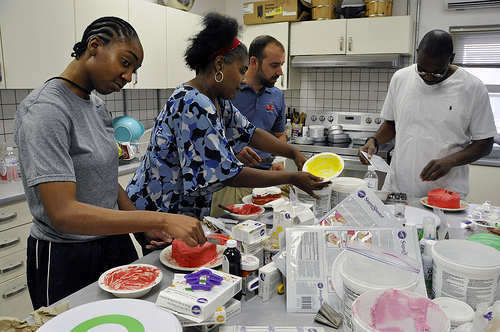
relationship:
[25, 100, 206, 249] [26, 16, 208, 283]
arm of lady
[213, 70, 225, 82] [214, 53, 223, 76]
earring on ear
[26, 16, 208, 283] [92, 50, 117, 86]
lady has a cheek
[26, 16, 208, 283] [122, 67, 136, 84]
lady has a nose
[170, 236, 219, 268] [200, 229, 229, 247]
cake being iced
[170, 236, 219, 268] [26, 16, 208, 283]
cake iced by lady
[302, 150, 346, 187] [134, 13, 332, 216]
dish held by woman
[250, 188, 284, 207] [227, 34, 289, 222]
cake iced by man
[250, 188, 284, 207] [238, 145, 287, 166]
cake being iced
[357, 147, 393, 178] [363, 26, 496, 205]
paper held by man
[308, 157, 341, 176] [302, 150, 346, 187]
icing in bowl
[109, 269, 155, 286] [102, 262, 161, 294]
icing in container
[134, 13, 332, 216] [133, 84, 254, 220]
woman wearing top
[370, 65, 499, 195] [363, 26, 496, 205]
t-shirt on man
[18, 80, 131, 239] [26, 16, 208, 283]
t-shirt on lady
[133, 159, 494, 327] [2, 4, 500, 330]
cooking in kitchen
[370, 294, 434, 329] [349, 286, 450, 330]
pink icing in bucket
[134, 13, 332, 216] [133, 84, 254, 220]
woman wearing blouse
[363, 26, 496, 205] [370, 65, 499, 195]
man wearing t-shirt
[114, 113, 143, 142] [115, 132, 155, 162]
bowl in dish drain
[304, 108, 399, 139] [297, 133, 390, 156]
back of stove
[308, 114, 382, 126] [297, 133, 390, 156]
control knobs on stove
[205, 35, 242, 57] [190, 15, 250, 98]
hair band on woman's head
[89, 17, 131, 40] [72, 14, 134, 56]
corn rows in hair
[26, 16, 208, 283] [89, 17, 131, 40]
lady with corn rows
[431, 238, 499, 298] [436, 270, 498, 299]
plastic bowl has writing on it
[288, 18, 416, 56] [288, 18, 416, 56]
cabinet has cabinet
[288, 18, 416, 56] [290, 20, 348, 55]
cabinet has door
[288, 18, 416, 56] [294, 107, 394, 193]
cabinet over oven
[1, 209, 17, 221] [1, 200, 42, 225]
silver handle on drawer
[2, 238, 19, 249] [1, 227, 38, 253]
silver handle on drawer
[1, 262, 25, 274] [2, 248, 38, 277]
silver handle on drawer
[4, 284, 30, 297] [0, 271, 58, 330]
silver handle on drawer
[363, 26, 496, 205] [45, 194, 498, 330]
man looking at table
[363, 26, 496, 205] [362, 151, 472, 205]
man looking down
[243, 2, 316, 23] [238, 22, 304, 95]
carboard box on cabinet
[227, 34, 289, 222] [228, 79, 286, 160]
man in shirt